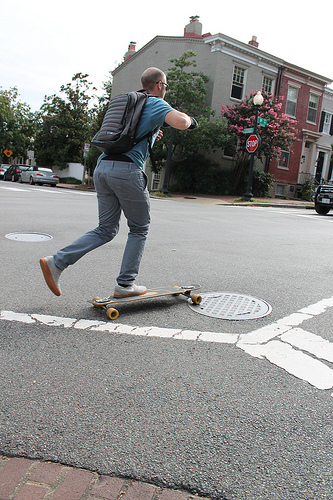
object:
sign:
[245, 134, 259, 154]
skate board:
[87, 282, 202, 320]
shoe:
[38, 254, 62, 296]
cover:
[187, 292, 272, 320]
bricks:
[0, 453, 231, 500]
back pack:
[90, 88, 159, 174]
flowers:
[221, 86, 302, 162]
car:
[19, 165, 60, 187]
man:
[39, 66, 198, 300]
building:
[100, 15, 333, 202]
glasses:
[155, 78, 169, 90]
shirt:
[96, 94, 173, 171]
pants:
[51, 159, 152, 286]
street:
[0, 181, 332, 496]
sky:
[0, 2, 333, 123]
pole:
[241, 105, 259, 202]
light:
[252, 91, 263, 107]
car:
[3, 164, 30, 182]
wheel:
[106, 307, 119, 320]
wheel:
[192, 294, 202, 305]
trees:
[146, 49, 239, 196]